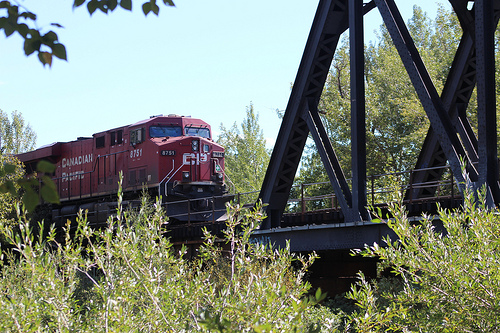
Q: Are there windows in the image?
A: Yes, there is a window.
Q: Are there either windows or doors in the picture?
A: Yes, there is a window.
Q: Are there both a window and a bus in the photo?
A: No, there is a window but no buses.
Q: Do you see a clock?
A: No, there are no clocks.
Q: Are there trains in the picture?
A: Yes, there is a train.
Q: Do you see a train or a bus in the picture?
A: Yes, there is a train.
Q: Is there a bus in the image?
A: No, there are no buses.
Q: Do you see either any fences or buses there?
A: No, there are no buses or fences.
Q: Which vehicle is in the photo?
A: The vehicle is a train.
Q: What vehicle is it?
A: The vehicle is a train.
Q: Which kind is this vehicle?
A: That is a train.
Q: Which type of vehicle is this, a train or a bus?
A: That is a train.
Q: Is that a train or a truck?
A: That is a train.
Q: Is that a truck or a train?
A: That is a train.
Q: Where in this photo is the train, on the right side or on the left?
A: The train is on the left of the image.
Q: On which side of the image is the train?
A: The train is on the left of the image.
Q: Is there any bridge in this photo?
A: Yes, there is a bridge.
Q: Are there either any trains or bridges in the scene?
A: Yes, there is a bridge.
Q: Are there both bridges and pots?
A: No, there is a bridge but no pots.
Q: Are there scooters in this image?
A: No, there are no scooters.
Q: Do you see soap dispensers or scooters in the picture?
A: No, there are no scooters or soap dispensers.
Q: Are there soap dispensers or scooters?
A: No, there are no scooters or soap dispensers.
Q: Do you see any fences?
A: No, there are no fences.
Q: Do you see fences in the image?
A: No, there are no fences.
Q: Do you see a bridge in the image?
A: Yes, there is a bridge.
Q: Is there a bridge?
A: Yes, there is a bridge.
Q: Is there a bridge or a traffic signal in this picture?
A: Yes, there is a bridge.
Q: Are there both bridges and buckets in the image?
A: No, there is a bridge but no buckets.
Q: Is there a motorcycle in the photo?
A: No, there are no motorcycles.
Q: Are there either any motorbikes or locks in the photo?
A: No, there are no motorbikes or locks.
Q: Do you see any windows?
A: Yes, there is a window.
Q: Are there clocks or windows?
A: Yes, there is a window.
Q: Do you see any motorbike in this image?
A: No, there are no motorcycles.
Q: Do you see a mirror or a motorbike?
A: No, there are no motorcycles or mirrors.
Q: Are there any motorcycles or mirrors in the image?
A: No, there are no motorcycles or mirrors.